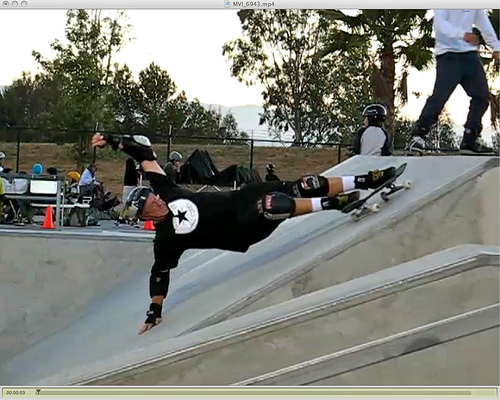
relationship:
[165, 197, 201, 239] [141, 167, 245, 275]
logo on shirt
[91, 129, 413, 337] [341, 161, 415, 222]
skater on board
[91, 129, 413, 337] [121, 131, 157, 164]
skater with elbowpad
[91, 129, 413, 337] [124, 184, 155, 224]
skater wearing helmet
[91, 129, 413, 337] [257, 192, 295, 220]
skater with kneepad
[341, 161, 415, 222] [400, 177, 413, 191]
board has wheel